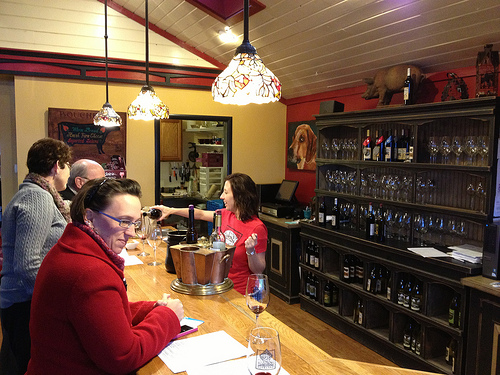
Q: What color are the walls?
A: Yellow and red.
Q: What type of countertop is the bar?
A: Wood.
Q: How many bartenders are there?
A: One.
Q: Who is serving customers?
A: Bartender.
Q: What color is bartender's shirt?
A: Red.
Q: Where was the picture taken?
A: At a bar.